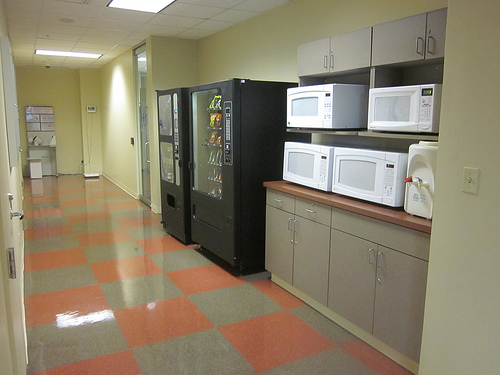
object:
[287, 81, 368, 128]
microwave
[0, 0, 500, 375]
break room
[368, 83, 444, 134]
microwave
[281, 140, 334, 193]
microwave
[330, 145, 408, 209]
microwave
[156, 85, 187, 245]
vending machine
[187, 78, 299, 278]
vending machine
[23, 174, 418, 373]
floor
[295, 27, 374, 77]
cabinets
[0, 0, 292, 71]
tiles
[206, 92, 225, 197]
snacks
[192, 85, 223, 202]
door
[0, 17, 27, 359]
door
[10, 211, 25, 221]
handle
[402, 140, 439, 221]
dispenser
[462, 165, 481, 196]
light switch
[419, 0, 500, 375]
wall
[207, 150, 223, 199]
candy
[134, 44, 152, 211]
door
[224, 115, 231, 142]
buttons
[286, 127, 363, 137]
shelf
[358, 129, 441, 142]
shelf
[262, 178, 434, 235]
shelf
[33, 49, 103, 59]
light